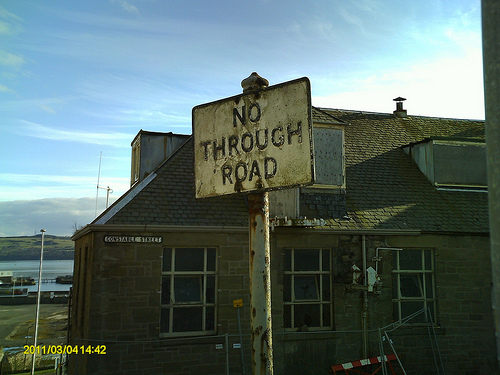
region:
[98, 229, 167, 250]
A sign on the wall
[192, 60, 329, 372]
The sign in the ground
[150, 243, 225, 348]
The window on the side of the house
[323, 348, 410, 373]
The construction sign of the wall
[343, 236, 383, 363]
The pipes coming out of the building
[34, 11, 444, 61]
The sky is the color blue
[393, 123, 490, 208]
The cooler on top of the roof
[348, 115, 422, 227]
The roof is the color brown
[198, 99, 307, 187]
The sign says " No through road"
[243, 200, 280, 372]
The pole in the ground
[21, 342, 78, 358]
Date stamp of photograph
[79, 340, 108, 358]
Time stamp of photograph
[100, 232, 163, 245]
Street name sign on building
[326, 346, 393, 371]
Red and white barrier rail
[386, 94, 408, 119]
Metal chimney on building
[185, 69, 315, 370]
Metal traffic warning sign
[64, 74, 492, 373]
Stone building near shore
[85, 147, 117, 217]
Metal antenna on roof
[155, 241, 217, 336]
Wood framed window on building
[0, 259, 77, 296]
Waterway in background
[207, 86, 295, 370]
the old sign on the pole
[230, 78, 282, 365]
the pole that the sign is on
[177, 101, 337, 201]
the sign that says no through road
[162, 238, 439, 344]
three windows in a row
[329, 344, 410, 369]
the caution barrier by the building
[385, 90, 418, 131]
the air vent on the roof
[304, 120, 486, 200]
the boarded up windows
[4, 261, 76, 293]
the water in the background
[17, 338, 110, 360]
the time and date stamp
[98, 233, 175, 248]
the sign on the building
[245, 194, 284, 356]
the pole is rusty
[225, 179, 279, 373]
the pole is rusty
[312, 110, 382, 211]
the roof is brown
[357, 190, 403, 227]
the roof is brown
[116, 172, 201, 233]
the roof is brown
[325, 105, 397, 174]
the roof is brown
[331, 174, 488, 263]
the roof is brown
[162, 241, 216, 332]
A window on the building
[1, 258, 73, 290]
A body of water behind the building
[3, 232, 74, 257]
A hill beyond the body of water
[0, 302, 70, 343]
A field behind the building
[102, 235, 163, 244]
A street sign on the building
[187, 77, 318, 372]
An old sign in front of the building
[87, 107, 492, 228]
The roof of the building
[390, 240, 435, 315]
The window is broken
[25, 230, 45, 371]
A silver pole behind the building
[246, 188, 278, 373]
A pole holding the traffic sign